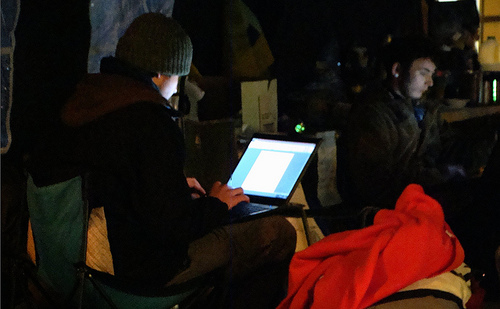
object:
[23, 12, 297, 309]
man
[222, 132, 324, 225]
laptop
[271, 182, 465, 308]
blanket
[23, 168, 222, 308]
chair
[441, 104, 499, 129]
table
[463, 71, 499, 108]
boxes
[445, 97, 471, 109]
dishes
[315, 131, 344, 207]
paper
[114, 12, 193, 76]
hat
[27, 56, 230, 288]
coat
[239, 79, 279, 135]
menu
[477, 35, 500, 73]
jug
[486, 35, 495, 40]
top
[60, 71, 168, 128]
hood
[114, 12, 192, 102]
head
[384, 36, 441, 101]
head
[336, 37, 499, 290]
man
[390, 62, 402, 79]
ear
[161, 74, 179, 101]
face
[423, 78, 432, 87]
nose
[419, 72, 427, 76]
eye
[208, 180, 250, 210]
hand